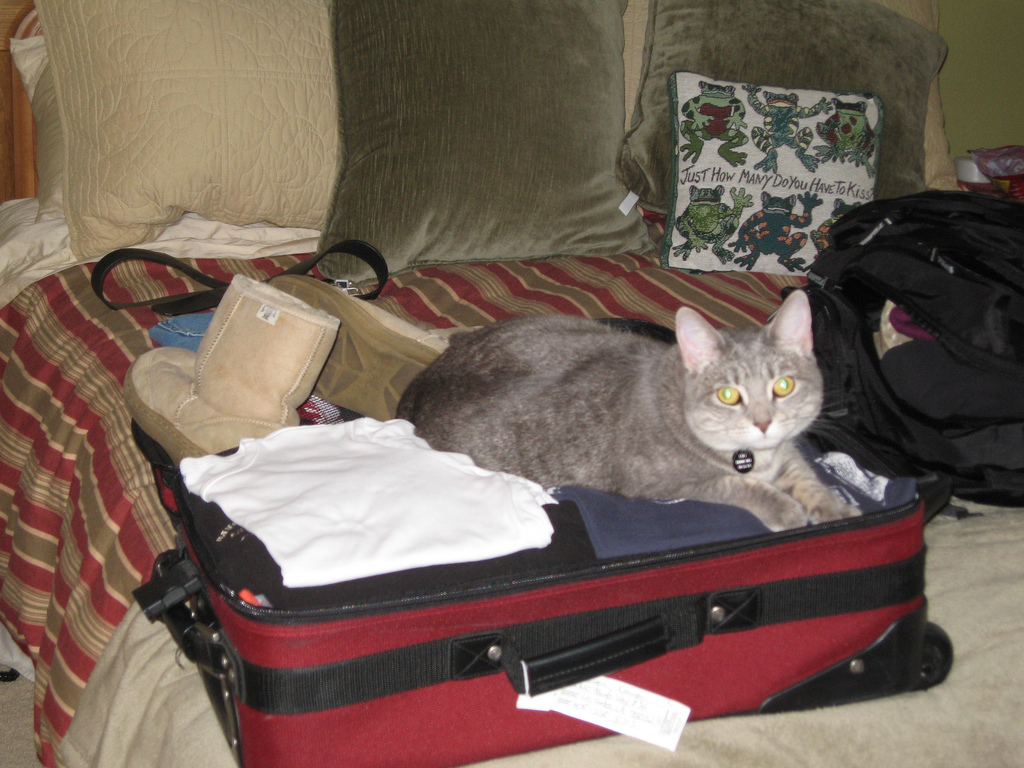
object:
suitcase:
[130, 310, 943, 768]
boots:
[124, 273, 343, 467]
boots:
[256, 271, 449, 424]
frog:
[812, 97, 872, 174]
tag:
[514, 669, 695, 753]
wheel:
[906, 621, 954, 691]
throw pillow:
[664, 66, 891, 282]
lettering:
[680, 165, 877, 203]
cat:
[389, 286, 865, 535]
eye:
[768, 369, 803, 406]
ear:
[672, 306, 729, 374]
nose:
[747, 411, 776, 432]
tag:
[732, 447, 757, 475]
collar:
[730, 448, 758, 474]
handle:
[477, 586, 770, 698]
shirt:
[204, 503, 600, 610]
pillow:
[664, 66, 888, 278]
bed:
[0, 0, 1024, 768]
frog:
[741, 82, 834, 174]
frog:
[728, 192, 823, 273]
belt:
[90, 238, 390, 318]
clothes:
[178, 413, 913, 612]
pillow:
[610, 0, 950, 216]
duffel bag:
[777, 183, 1024, 513]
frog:
[676, 80, 752, 167]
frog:
[813, 97, 881, 180]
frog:
[673, 186, 756, 265]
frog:
[727, 186, 824, 273]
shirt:
[174, 414, 559, 589]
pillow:
[33, 1, 341, 266]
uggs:
[128, 278, 347, 476]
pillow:
[308, 0, 681, 279]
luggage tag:
[474, 598, 767, 696]